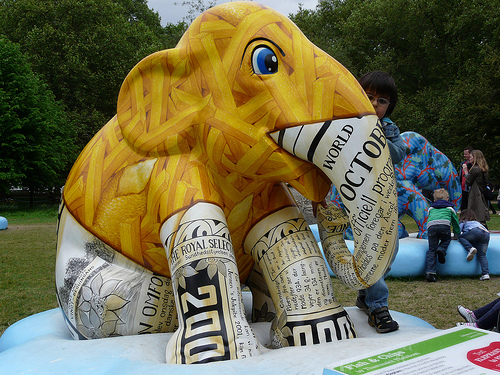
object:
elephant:
[53, 1, 398, 364]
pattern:
[165, 62, 244, 171]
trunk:
[316, 147, 398, 290]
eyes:
[251, 47, 279, 75]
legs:
[158, 184, 272, 365]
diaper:
[68, 256, 145, 339]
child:
[357, 75, 406, 334]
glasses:
[362, 97, 394, 108]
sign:
[365, 341, 467, 374]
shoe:
[368, 305, 399, 334]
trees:
[1, 18, 155, 219]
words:
[282, 251, 329, 320]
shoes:
[479, 273, 490, 281]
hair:
[359, 71, 398, 104]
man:
[462, 146, 473, 186]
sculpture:
[329, 130, 461, 240]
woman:
[465, 150, 492, 229]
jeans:
[358, 275, 389, 314]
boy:
[424, 188, 462, 282]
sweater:
[425, 201, 462, 237]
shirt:
[458, 220, 488, 233]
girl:
[458, 209, 491, 280]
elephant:
[326, 131, 462, 238]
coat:
[461, 184, 491, 221]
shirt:
[461, 165, 471, 187]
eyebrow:
[239, 37, 286, 67]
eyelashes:
[248, 60, 255, 76]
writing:
[360, 206, 396, 280]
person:
[456, 293, 499, 339]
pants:
[474, 298, 500, 330]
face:
[363, 91, 390, 119]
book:
[322, 324, 500, 373]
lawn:
[6, 203, 74, 338]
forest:
[404, 30, 500, 166]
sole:
[452, 307, 470, 322]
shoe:
[456, 303, 481, 322]